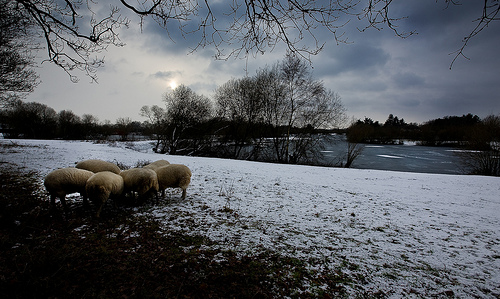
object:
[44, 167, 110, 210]
sheep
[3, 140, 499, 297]
snow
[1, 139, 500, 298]
ground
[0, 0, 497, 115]
sky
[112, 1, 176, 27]
limb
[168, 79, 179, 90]
sun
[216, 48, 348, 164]
trees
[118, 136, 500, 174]
water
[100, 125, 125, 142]
house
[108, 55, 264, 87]
clouds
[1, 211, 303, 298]
leaves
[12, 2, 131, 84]
branches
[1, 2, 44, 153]
tree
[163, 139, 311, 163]
trunks